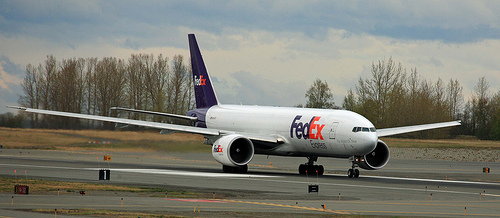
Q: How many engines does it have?
A: Two.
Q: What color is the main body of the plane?
A: White.